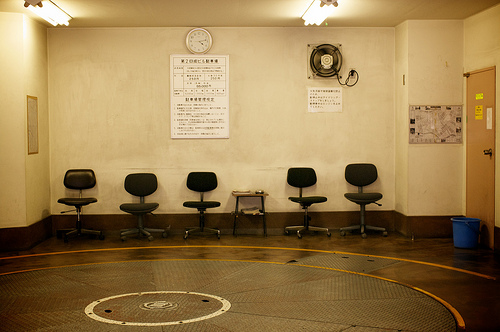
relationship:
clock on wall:
[185, 27, 214, 54] [67, 34, 367, 209]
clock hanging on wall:
[185, 27, 214, 54] [236, 39, 301, 128]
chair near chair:
[56, 166, 105, 245] [118, 170, 170, 242]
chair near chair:
[118, 170, 170, 242] [181, 170, 224, 239]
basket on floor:
[450, 217, 483, 248] [4, 210, 498, 322]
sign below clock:
[167, 55, 232, 140] [180, 25, 213, 53]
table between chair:
[226, 184, 271, 242] [279, 160, 334, 239]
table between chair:
[226, 184, 271, 242] [179, 164, 226, 244]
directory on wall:
[170, 55, 232, 139] [58, 32, 398, 213]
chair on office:
[181, 171, 222, 240] [51, 160, 400, 245]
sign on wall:
[167, 48, 232, 140] [45, 25, 395, 232]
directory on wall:
[171, 50, 234, 137] [389, 77, 465, 164]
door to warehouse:
[466, 66, 493, 242] [5, 3, 491, 326]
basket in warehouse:
[450, 217, 483, 248] [5, 3, 491, 326]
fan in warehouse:
[305, 40, 360, 87] [5, 3, 491, 326]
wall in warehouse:
[47, 30, 169, 164] [5, 3, 491, 326]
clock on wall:
[185, 27, 214, 54] [58, 32, 398, 213]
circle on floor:
[77, 284, 234, 330] [5, 238, 498, 328]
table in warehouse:
[232, 189, 268, 238] [5, 3, 491, 326]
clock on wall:
[182, 25, 217, 56] [52, 30, 465, 220]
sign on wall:
[300, 79, 353, 112] [138, 50, 282, 165]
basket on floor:
[442, 210, 483, 248] [2, 227, 498, 329]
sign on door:
[474, 97, 483, 99] [461, 79, 483, 227]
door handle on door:
[482, 145, 492, 162] [464, 67, 499, 227]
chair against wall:
[339, 163, 389, 239] [63, 50, 393, 175]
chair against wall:
[282, 166, 333, 236] [45, 25, 395, 232]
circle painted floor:
[84, 281, 235, 329] [235, 257, 397, 315]